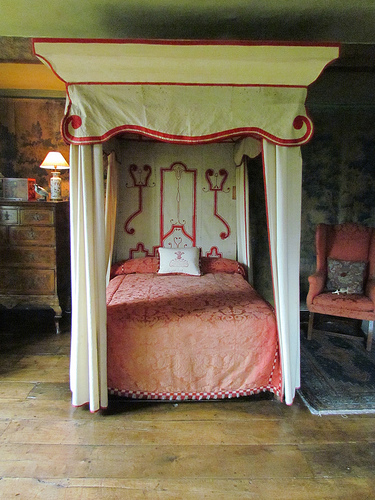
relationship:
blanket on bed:
[107, 256, 286, 403] [40, 42, 340, 410]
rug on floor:
[287, 323, 374, 419] [0, 313, 373, 498]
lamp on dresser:
[40, 154, 66, 198] [4, 205, 70, 334]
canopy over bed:
[30, 37, 343, 409] [40, 42, 340, 410]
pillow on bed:
[201, 257, 248, 276] [40, 42, 340, 410]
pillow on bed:
[153, 247, 203, 275] [40, 42, 340, 410]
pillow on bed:
[112, 254, 157, 276] [40, 42, 340, 410]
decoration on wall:
[120, 143, 247, 260] [0, 38, 369, 327]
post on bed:
[284, 93, 295, 411] [40, 42, 340, 410]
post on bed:
[233, 141, 252, 276] [40, 42, 340, 410]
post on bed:
[66, 78, 102, 417] [40, 42, 340, 410]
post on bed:
[92, 123, 124, 276] [40, 42, 340, 410]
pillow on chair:
[325, 258, 369, 294] [302, 218, 374, 353]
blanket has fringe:
[107, 256, 286, 403] [105, 342, 284, 400]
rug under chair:
[287, 323, 374, 419] [302, 218, 374, 353]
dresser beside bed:
[4, 205, 70, 334] [40, 42, 340, 410]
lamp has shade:
[40, 154, 66, 198] [40, 154, 69, 172]